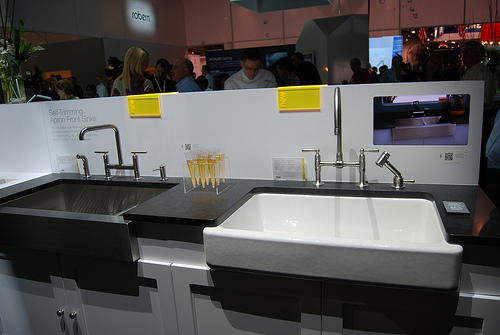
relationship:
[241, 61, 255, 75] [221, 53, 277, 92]
eye of man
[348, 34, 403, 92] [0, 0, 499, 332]
person on showroom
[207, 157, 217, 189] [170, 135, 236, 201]
shot on tray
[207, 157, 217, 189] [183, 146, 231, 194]
shot on container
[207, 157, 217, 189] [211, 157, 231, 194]
shot on tray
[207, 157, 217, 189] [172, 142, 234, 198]
shot on tray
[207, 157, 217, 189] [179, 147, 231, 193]
shot on tray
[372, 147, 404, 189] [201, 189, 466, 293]
sprayer on sink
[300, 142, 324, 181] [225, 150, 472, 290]
knob on sink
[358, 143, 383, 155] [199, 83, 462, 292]
knob on sink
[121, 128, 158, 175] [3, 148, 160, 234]
knob on sink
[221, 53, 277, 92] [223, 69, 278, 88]
man wearing a shirt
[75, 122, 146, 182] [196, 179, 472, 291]
faucet on a sink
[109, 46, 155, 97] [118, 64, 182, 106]
people wearing a shirt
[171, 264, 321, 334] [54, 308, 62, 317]
cabinet with nob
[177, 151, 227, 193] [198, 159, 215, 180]
container with test tubes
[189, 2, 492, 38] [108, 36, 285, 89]
cabinets behind people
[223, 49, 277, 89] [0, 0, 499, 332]
man standing on a showroom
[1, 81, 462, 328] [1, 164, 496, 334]
sinks in counter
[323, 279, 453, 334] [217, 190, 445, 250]
cabinet under sink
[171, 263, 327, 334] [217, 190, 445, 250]
cabinet under sink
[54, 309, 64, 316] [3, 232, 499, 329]
nob on cabinet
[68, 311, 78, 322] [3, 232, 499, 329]
nob on cabinet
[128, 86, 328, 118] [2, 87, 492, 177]
post on wall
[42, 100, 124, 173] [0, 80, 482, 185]
sign on wall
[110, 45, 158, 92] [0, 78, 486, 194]
people behind wall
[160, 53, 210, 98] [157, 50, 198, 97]
head of man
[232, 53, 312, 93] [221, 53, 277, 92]
face of man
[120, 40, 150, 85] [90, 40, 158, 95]
head of woman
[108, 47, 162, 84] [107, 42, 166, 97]
hair of woman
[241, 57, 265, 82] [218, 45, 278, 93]
forehead of man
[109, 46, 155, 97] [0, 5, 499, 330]
people walking around showroom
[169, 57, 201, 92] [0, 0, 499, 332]
man standing in showroom